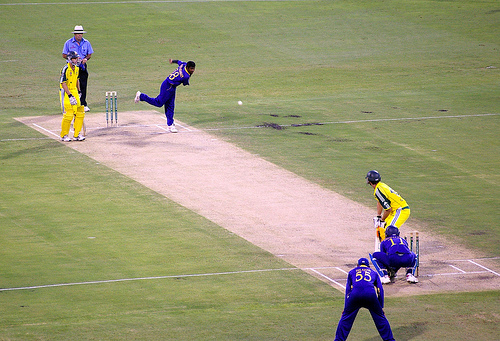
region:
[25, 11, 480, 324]
a game of cricket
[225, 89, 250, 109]
this is a ball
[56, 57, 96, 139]
man wearing a yellow uniform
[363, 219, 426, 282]
a man squatting down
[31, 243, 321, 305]
white line on the ground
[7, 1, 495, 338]
the game of cricket is being played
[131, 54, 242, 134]
the bowler is looking at the ball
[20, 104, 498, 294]
the bowling pitch is brown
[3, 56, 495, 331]
the grasses in the field are green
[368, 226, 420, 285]
the keeper in his ready position behind the stumps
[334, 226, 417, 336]
the fielder is standing behind the keeper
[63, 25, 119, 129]
the umpire is standing behind the stumps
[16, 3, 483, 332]
A cricket match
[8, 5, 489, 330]
A cricket match is taking place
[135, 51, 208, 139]
The player is wearing a uniform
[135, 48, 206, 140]
The player is wearing a blue uniform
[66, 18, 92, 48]
The man has a hat on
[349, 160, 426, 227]
The batter is waiting for the pitch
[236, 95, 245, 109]
Ball is in the air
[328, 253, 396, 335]
Player looking on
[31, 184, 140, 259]
Large patch of grass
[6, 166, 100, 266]
Large patch of green grass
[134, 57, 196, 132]
man in a blue outfit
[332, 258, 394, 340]
man in a blue outfit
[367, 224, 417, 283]
man in a blue outfit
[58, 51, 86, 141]
man in a yellow outfit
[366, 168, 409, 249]
man in a yellow outfit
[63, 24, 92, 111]
man in a white hat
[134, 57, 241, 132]
man in blue throwing a white ball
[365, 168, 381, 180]
blue plastic helmet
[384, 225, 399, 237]
blue plastic helmet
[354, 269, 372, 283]
the number 55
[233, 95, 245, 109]
white ball in the air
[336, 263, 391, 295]
man wearing a blue jersey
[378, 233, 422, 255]
man wearing a blue jersey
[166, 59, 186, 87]
man wearing a blue jersey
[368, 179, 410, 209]
man wearing a yellow jersey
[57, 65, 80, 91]
man wearing a yellow jersey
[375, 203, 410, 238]
man wearing yellow pants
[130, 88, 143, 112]
man wearing white shoes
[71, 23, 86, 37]
man wearing a white hat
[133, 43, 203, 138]
pitcher in blue throwing the ball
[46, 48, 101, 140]
a baseball player dressed in yellow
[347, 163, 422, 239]
a baseball player dressed in yellow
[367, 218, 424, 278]
the catcher behind home plate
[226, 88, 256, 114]
white ball in the middle of the air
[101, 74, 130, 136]
bunch of bats with a m on it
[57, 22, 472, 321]
bunch of baseball players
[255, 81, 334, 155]
dirt patches in the ground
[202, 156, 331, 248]
dirt on the ground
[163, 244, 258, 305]
line on the ground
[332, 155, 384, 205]
head of the person